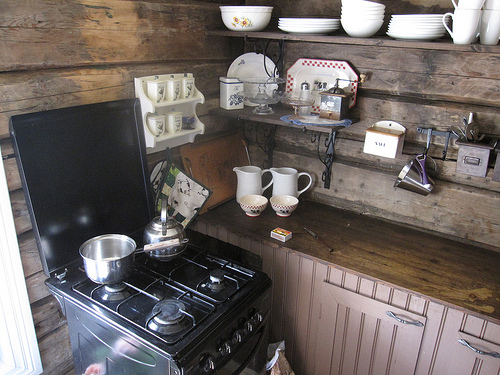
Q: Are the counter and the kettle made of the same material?
A: No, the counter is made of wood and the kettle is made of metal.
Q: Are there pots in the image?
A: Yes, there is a pot.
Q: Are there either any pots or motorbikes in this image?
A: Yes, there is a pot.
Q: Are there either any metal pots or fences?
A: Yes, there is a metal pot.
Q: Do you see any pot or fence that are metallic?
A: Yes, the pot is metallic.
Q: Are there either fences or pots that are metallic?
A: Yes, the pot is metallic.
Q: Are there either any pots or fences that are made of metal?
A: Yes, the pot is made of metal.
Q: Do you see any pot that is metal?
A: Yes, there is a metal pot.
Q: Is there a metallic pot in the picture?
A: Yes, there is a metal pot.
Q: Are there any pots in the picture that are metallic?
A: Yes, there is a pot that is metallic.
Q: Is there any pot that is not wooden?
A: Yes, there is a metallic pot.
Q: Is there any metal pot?
A: Yes, there is a pot that is made of metal.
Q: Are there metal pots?
A: Yes, there is a pot that is made of metal.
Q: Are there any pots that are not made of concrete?
A: Yes, there is a pot that is made of metal.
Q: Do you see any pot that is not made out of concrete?
A: Yes, there is a pot that is made of metal.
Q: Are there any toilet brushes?
A: No, there are no toilet brushes.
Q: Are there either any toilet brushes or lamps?
A: No, there are no toilet brushes or lamps.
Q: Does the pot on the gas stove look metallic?
A: Yes, the pot is metallic.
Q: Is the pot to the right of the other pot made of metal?
A: Yes, the pot is made of metal.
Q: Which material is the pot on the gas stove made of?
A: The pot is made of metal.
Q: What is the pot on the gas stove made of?
A: The pot is made of metal.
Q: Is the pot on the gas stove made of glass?
A: No, the pot is made of metal.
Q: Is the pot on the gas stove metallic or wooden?
A: The pot is metallic.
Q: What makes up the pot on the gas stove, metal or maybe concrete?
A: The pot is made of metal.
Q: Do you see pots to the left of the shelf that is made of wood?
A: Yes, there is a pot to the left of the shelf.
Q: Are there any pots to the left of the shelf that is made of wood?
A: Yes, there is a pot to the left of the shelf.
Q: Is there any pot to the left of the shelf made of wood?
A: Yes, there is a pot to the left of the shelf.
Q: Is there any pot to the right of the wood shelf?
A: No, the pot is to the left of the shelf.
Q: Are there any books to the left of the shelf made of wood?
A: No, there is a pot to the left of the shelf.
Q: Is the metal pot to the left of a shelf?
A: Yes, the pot is to the left of a shelf.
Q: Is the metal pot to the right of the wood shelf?
A: No, the pot is to the left of the shelf.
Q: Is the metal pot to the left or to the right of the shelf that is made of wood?
A: The pot is to the left of the shelf.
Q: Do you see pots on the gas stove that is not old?
A: Yes, there is a pot on the gas stove.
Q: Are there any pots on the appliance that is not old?
A: Yes, there is a pot on the gas stove.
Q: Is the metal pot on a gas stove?
A: Yes, the pot is on a gas stove.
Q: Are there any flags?
A: No, there are no flags.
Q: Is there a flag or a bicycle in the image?
A: No, there are no flags or bicycles.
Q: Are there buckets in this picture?
A: No, there are no buckets.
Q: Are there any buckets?
A: No, there are no buckets.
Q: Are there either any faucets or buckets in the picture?
A: No, there are no buckets or faucets.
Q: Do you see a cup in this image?
A: Yes, there is a cup.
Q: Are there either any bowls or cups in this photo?
A: Yes, there is a cup.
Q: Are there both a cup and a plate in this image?
A: Yes, there are both a cup and a plate.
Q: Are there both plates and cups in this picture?
A: Yes, there are both a cup and a plate.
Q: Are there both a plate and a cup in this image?
A: Yes, there are both a cup and a plate.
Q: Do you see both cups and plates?
A: Yes, there are both a cup and a plate.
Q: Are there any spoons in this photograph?
A: No, there are no spoons.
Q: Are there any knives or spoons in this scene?
A: No, there are no spoons or knives.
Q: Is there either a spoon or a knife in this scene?
A: No, there are no spoons or knives.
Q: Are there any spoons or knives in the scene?
A: No, there are no spoons or knives.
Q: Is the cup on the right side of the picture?
A: Yes, the cup is on the right of the image.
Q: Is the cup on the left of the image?
A: No, the cup is on the right of the image.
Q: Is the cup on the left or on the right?
A: The cup is on the right of the image.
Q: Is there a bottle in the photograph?
A: No, there are no bottles.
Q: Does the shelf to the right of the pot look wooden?
A: Yes, the shelf is wooden.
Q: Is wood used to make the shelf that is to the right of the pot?
A: Yes, the shelf is made of wood.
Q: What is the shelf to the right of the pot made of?
A: The shelf is made of wood.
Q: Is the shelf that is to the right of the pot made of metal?
A: No, the shelf is made of wood.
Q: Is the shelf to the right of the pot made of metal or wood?
A: The shelf is made of wood.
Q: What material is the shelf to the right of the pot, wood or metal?
A: The shelf is made of wood.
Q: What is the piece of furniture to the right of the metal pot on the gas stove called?
A: The piece of furniture is a shelf.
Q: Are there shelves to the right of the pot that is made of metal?
A: Yes, there is a shelf to the right of the pot.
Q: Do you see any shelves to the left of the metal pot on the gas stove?
A: No, the shelf is to the right of the pot.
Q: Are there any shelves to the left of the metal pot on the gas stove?
A: No, the shelf is to the right of the pot.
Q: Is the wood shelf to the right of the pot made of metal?
A: Yes, the shelf is to the right of the pot.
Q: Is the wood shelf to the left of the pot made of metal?
A: No, the shelf is to the right of the pot.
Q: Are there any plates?
A: Yes, there is a plate.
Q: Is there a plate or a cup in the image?
A: Yes, there is a plate.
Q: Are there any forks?
A: No, there are no forks.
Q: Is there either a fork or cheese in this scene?
A: No, there are no forks or cheese.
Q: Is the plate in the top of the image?
A: Yes, the plate is in the top of the image.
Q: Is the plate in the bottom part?
A: No, the plate is in the top of the image.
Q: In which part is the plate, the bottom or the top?
A: The plate is in the top of the image.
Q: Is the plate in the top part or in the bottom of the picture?
A: The plate is in the top of the image.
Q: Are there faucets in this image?
A: No, there are no faucets.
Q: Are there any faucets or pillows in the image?
A: No, there are no faucets or pillows.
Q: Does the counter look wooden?
A: Yes, the counter is wooden.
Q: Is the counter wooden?
A: Yes, the counter is wooden.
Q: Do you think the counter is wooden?
A: Yes, the counter is wooden.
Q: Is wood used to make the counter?
A: Yes, the counter is made of wood.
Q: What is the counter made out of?
A: The counter is made of wood.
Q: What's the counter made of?
A: The counter is made of wood.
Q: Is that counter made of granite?
A: No, the counter is made of wood.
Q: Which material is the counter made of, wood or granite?
A: The counter is made of wood.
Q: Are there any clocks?
A: No, there are no clocks.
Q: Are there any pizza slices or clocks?
A: No, there are no clocks or pizza slices.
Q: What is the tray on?
A: The tray is on the counter.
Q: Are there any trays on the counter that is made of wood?
A: Yes, there is a tray on the counter.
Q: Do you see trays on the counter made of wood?
A: Yes, there is a tray on the counter.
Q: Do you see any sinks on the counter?
A: No, there is a tray on the counter.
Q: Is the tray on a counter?
A: Yes, the tray is on a counter.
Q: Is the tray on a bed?
A: No, the tray is on a counter.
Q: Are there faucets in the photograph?
A: No, there are no faucets.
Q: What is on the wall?
A: The shelf is on the wall.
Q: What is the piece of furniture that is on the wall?
A: The piece of furniture is a shelf.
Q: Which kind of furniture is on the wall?
A: The piece of furniture is a shelf.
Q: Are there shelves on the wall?
A: Yes, there is a shelf on the wall.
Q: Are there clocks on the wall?
A: No, there is a shelf on the wall.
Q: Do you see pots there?
A: Yes, there is a pot.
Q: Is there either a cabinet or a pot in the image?
A: Yes, there is a pot.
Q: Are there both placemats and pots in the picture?
A: No, there is a pot but no placemats.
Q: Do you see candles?
A: No, there are no candles.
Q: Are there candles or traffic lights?
A: No, there are no candles or traffic lights.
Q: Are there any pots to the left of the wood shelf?
A: Yes, there is a pot to the left of the shelf.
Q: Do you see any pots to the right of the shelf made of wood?
A: No, the pot is to the left of the shelf.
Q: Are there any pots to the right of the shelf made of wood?
A: No, the pot is to the left of the shelf.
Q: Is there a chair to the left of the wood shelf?
A: No, there is a pot to the left of the shelf.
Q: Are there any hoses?
A: No, there are no hoses.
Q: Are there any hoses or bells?
A: No, there are no hoses or bells.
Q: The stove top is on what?
A: The stove top is on the gas stove.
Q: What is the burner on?
A: The stove top is on the gas stove.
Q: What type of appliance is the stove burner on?
A: The stove burner is on the gas stove.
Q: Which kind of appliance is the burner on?
A: The stove burner is on the gas stove.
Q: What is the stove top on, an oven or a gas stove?
A: The stove top is on a gas stove.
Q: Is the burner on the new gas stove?
A: Yes, the burner is on the gas stove.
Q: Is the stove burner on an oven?
A: No, the stove burner is on the gas stove.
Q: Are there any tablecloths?
A: No, there are no tablecloths.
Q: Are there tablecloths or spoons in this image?
A: No, there are no tablecloths or spoons.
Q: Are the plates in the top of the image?
A: Yes, the plates are in the top of the image.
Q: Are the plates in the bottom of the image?
A: No, the plates are in the top of the image.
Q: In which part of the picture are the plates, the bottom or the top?
A: The plates are in the top of the image.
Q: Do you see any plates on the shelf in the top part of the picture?
A: Yes, there are plates on the shelf.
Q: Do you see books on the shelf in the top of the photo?
A: No, there are plates on the shelf.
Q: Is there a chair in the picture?
A: No, there are no chairs.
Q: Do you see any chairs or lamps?
A: No, there are no chairs or lamps.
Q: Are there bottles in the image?
A: No, there are no bottles.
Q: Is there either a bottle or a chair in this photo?
A: No, there are no bottles or chairs.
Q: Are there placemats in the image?
A: No, there are no placemats.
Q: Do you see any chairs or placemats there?
A: No, there are no placemats or chairs.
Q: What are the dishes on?
A: The dishes are on the shelf.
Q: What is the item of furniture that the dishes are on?
A: The piece of furniture is a shelf.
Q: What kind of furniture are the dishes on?
A: The dishes are on the shelf.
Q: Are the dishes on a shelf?
A: Yes, the dishes are on a shelf.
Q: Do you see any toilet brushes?
A: No, there are no toilet brushes.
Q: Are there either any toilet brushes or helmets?
A: No, there are no toilet brushes or helmets.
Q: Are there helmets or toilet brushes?
A: No, there are no toilet brushes or helmets.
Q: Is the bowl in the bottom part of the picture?
A: No, the bowl is in the top of the image.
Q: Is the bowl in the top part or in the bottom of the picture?
A: The bowl is in the top of the image.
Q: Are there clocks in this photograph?
A: No, there are no clocks.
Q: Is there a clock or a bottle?
A: No, there are no clocks or bottles.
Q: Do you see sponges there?
A: No, there are no sponges.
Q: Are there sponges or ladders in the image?
A: No, there are no sponges or ladders.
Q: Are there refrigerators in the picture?
A: No, there are no refrigerators.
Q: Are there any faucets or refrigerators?
A: No, there are no refrigerators or faucets.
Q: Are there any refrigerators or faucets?
A: No, there are no refrigerators or faucets.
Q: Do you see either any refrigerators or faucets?
A: No, there are no refrigerators or faucets.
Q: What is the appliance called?
A: The appliance is a gas stove.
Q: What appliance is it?
A: The appliance is a gas stove.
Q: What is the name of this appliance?
A: This is a gas stove.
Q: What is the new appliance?
A: The appliance is a gas stove.